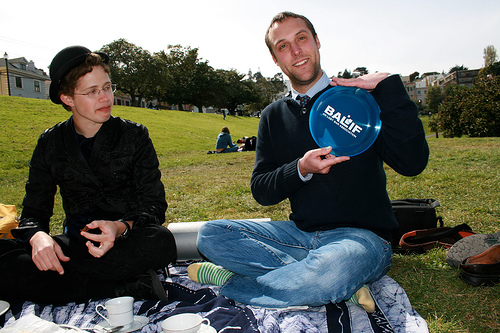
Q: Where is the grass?
A: On the ground.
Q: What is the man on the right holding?
A: A frisbee.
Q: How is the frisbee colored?
A: Blue.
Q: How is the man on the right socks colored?
A: Green and yellow.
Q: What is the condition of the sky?
A: Clear and overcast.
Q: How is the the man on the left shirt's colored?
A: Black.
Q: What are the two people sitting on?
A: A blanket.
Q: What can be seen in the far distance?
A: A house and trees.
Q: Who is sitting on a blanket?
A: A couple of people.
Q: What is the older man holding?
A: A frisbee.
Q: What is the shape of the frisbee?
A: Round.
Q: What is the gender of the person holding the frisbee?
A: Male.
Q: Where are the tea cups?
A: On the blanket.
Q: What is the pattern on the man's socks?
A: Stripes.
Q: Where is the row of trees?
A: In front of the buildings.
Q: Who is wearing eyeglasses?
A: The boy.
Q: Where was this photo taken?
A: In a grassy field.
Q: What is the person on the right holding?
A: A frisbee.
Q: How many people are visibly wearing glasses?
A: One.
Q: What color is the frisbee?
A: Blue.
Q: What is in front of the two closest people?
A: Tea cups.